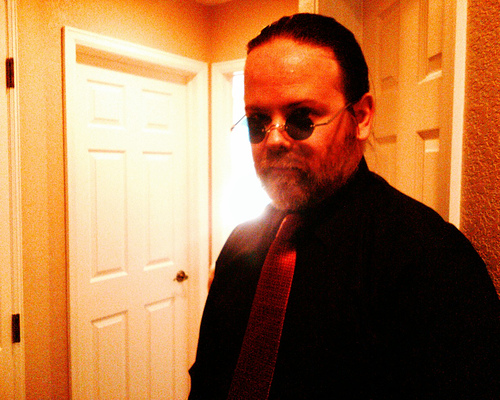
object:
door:
[351, 1, 456, 237]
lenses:
[284, 110, 315, 140]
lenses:
[245, 114, 265, 144]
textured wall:
[458, 2, 499, 294]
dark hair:
[244, 14, 349, 50]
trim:
[5, 3, 42, 398]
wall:
[447, 1, 497, 284]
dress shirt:
[178, 161, 500, 399]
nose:
[264, 113, 294, 153]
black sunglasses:
[239, 117, 312, 145]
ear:
[354, 90, 375, 140]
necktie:
[229, 210, 306, 400]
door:
[61, 30, 209, 398]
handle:
[176, 270, 186, 282]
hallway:
[1, 0, 498, 398]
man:
[180, 11, 498, 400]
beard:
[247, 114, 360, 212]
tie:
[228, 216, 303, 396]